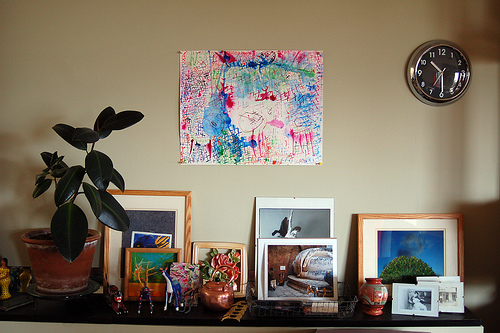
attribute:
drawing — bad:
[178, 47, 325, 168]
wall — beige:
[2, 1, 497, 332]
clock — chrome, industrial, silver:
[404, 36, 473, 109]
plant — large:
[34, 106, 145, 258]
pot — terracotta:
[22, 226, 101, 295]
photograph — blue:
[377, 232, 446, 278]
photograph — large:
[264, 242, 337, 301]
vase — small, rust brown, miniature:
[360, 277, 387, 315]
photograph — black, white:
[392, 284, 440, 317]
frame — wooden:
[104, 190, 190, 302]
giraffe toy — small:
[161, 268, 184, 313]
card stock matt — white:
[364, 220, 457, 279]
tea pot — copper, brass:
[197, 266, 238, 313]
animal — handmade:
[137, 282, 155, 316]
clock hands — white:
[432, 62, 447, 92]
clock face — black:
[416, 46, 470, 101]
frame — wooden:
[192, 240, 247, 299]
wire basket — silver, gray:
[246, 283, 357, 316]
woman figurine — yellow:
[0, 257, 10, 297]